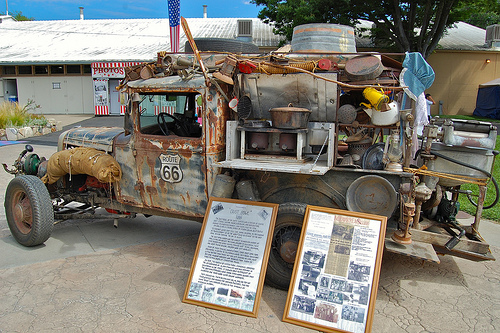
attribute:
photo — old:
[292, 297, 315, 314]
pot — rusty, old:
[262, 112, 313, 132]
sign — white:
[89, 67, 136, 80]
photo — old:
[348, 257, 375, 290]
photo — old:
[304, 246, 329, 273]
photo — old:
[315, 296, 342, 325]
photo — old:
[290, 293, 312, 316]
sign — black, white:
[157, 154, 182, 185]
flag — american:
[165, 2, 180, 52]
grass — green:
[439, 112, 495, 214]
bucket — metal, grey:
[286, 12, 381, 49]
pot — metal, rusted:
[263, 100, 318, 140]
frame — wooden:
[284, 200, 396, 330]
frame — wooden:
[178, 190, 280, 317]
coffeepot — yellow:
[361, 85, 391, 113]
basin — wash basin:
[289, 15, 379, 60]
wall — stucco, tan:
[440, 59, 466, 91]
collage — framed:
[287, 201, 387, 331]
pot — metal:
[345, 167, 403, 227]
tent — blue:
[469, 75, 499, 121]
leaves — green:
[251, 0, 499, 50]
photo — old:
[319, 276, 330, 287]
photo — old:
[314, 286, 344, 306]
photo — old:
[349, 258, 371, 280]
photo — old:
[303, 248, 323, 269]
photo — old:
[342, 304, 365, 323]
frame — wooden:
[280, 195, 390, 331]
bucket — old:
[343, 177, 404, 220]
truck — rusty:
[7, 64, 496, 288]